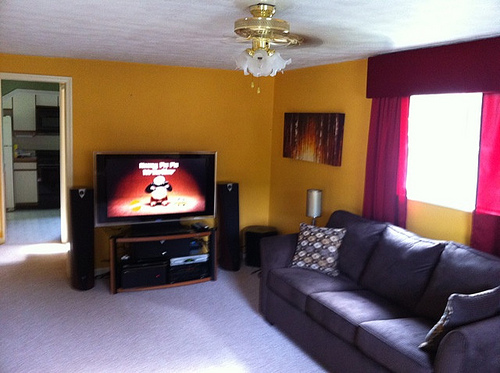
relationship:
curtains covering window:
[358, 34, 498, 258] [398, 70, 480, 248]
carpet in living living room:
[1, 255, 336, 371] [1, 0, 498, 371]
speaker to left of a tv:
[225, 160, 236, 256] [136, 149, 219, 304]